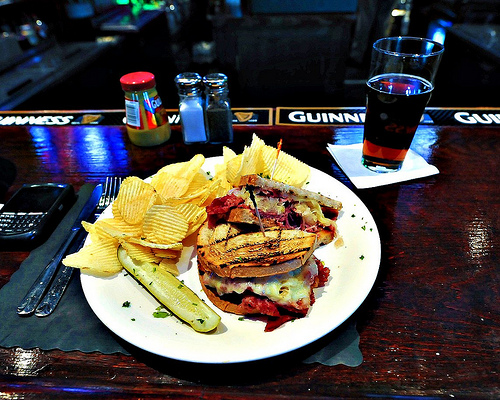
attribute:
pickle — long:
[114, 243, 220, 335]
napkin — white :
[335, 121, 440, 208]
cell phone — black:
[0, 178, 67, 242]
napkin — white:
[332, 142, 443, 189]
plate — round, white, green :
[81, 151, 383, 367]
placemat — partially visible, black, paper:
[3, 178, 363, 367]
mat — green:
[8, 197, 361, 369]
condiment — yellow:
[116, 65, 170, 144]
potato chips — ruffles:
[60, 148, 294, 271]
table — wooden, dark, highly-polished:
[2, 104, 494, 395]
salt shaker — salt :
[172, 65, 207, 144]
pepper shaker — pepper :
[199, 66, 234, 144]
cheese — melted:
[259, 277, 310, 304]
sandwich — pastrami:
[196, 176, 345, 327]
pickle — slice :
[114, 242, 210, 352]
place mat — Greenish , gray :
[50, 290, 117, 356]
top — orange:
[275, 137, 285, 156]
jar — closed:
[114, 66, 174, 146]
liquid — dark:
[357, 66, 430, 162]